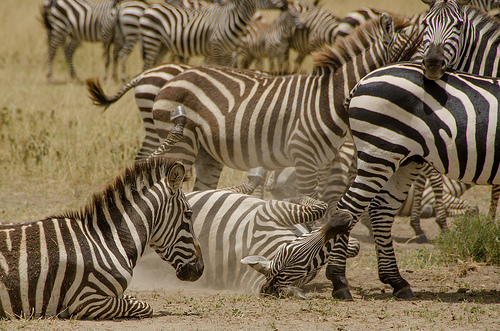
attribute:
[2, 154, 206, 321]
zebra — reclined 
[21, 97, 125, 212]
grass — tall , dried , golden 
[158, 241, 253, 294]
dust — kicked up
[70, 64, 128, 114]
moving tail — moving 